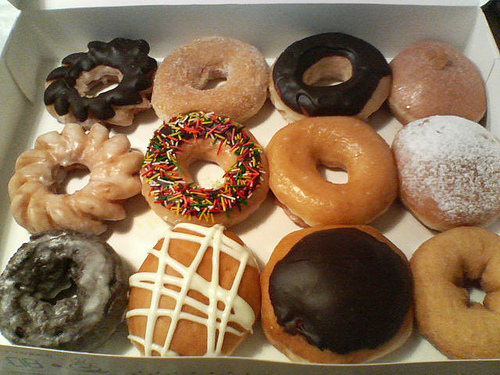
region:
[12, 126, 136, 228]
a tasty food item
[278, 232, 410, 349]
a roasted food item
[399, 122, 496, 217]
a sweet item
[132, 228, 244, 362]
crossed and tasty food item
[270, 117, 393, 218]
food item with oil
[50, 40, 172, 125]
highly roasted sweet item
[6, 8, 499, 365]
a plate holding sweet items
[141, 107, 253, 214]
a sweet arranged sweetly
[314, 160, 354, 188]
circle on the sweet item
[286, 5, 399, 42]
lightening in the holding plate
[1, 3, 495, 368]
a full cardboard box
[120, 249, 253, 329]
white lines of frosting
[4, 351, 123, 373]
some symbols on a box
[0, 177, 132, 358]
a glazed chocolate donut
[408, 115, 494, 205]
a dusting of powdered sugar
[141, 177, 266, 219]
an array of sprinkles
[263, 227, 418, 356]
donut with chocolate glaze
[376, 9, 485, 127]
a stuffed donut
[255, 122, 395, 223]
a donut with a hole in the center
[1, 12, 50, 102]
a white takeout box seam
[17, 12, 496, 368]
a box of doughnuts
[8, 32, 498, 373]
a dozen doughnuts in a box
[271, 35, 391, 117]
a chocolate doughnut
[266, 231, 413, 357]
a cream filled doughnut with chocolate glaze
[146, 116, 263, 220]
a plain doughnut with colorful sprinkles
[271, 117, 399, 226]
a doughnut glazed with honey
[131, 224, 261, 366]
a doughnut with white glaze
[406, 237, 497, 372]
a plain doughnut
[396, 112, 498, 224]
a doughnut with powdered sugar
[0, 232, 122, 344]
double chocolate doughnut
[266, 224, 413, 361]
Chocolate glazed donut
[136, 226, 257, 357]
White zigzag striped donut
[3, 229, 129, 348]
Delicious looking glaze covered donut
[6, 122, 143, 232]
Pinwheel shaped sugar glazed donut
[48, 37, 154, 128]
Chocolate glazed pinwheel donut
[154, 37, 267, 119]
Sugar coated round donut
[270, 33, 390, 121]
Donut glazed with chocolate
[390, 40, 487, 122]
Creme filled pastry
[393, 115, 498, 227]
Powder sugar coated pasry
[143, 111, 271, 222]
Donut glazed with chocolate and topped with colorful sprinkles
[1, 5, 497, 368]
a box of assorted donuts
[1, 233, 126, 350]
one chocolate old fashioned donut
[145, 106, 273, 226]
one donut with sprinkles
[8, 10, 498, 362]
eight donuts have a hole in the middle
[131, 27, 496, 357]
four donuts do not have holes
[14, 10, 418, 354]
three donuts have chocolate icing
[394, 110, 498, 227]
one donut with sprinkled sugar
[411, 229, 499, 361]
one plain cake donut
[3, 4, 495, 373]
donuts are in a white box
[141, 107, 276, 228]
donut has red, yellow, white and green sprinkles